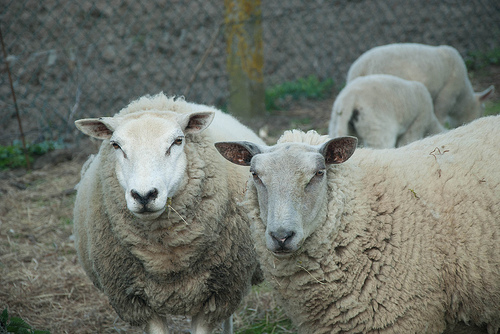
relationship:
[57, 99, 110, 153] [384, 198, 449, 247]
ears of sheep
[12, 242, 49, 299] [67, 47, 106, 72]
hay on ground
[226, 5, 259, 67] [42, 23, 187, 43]
post of fence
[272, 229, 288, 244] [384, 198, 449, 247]
nose of sheep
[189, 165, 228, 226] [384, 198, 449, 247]
wool of sheep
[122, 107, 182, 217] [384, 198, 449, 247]
head of sheep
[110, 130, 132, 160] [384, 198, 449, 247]
eye of sheep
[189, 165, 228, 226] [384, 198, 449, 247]
wool on sheep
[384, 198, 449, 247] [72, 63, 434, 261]
sheep in pen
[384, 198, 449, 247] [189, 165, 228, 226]
sheep have wool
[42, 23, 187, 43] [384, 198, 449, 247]
fence behind sheep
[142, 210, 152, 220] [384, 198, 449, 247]
mouth of sheep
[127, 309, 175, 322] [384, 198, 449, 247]
leg of sheep